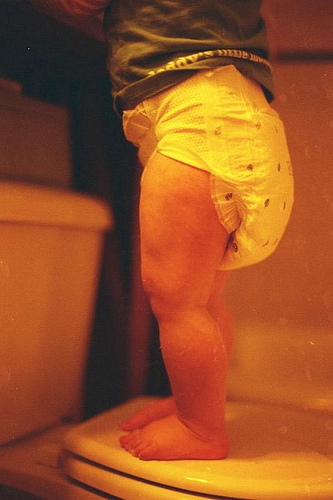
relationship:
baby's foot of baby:
[119, 412, 230, 460] [52, 3, 296, 458]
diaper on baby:
[110, 57, 298, 274] [119, 151, 293, 463]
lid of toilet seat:
[61, 392, 332, 499] [64, 393, 327, 498]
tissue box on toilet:
[2, 79, 75, 191] [61, 392, 331, 499]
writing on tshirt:
[147, 49, 272, 78] [104, 0, 275, 115]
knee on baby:
[140, 271, 210, 340] [52, 3, 296, 458]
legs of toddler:
[130, 204, 238, 429] [113, 43, 265, 490]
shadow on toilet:
[216, 383, 332, 460] [2, 181, 331, 494]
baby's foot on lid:
[119, 412, 230, 460] [61, 392, 332, 499]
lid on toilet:
[61, 392, 332, 499] [2, 181, 331, 494]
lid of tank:
[0, 179, 112, 229] [0, 207, 108, 438]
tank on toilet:
[0, 207, 108, 438] [3, 176, 110, 496]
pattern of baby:
[273, 153, 287, 180] [52, 3, 296, 458]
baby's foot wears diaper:
[119, 412, 230, 460] [123, 76, 314, 272]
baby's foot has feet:
[119, 412, 230, 460] [114, 399, 244, 461]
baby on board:
[52, 3, 296, 458] [75, 399, 311, 496]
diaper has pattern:
[110, 57, 298, 274] [259, 196, 276, 214]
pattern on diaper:
[218, 89, 286, 254] [110, 57, 298, 274]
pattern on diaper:
[273, 153, 287, 180] [125, 68, 299, 276]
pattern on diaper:
[257, 230, 275, 249] [110, 57, 298, 274]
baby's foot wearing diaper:
[119, 412, 230, 460] [125, 68, 299, 276]